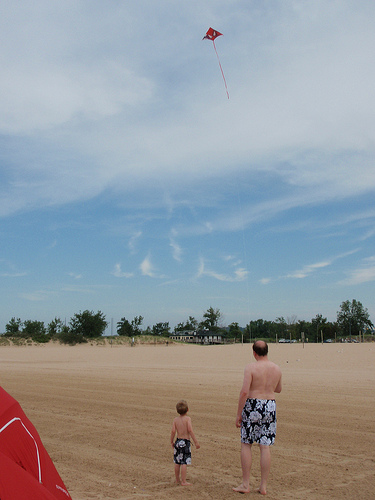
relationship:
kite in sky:
[201, 24, 231, 100] [0, 1, 374, 336]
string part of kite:
[211, 39, 231, 101] [201, 24, 231, 100]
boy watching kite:
[167, 398, 202, 487] [201, 24, 231, 100]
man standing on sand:
[234, 338, 283, 496] [0, 343, 374, 499]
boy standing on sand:
[167, 398, 202, 487] [0, 343, 374, 499]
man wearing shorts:
[234, 338, 283, 496] [239, 397, 277, 446]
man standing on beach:
[234, 338, 283, 496] [0, 343, 374, 499]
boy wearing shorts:
[167, 398, 202, 487] [174, 438, 193, 467]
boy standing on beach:
[167, 398, 202, 487] [0, 343, 374, 499]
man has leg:
[234, 338, 283, 496] [233, 441, 254, 494]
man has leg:
[234, 338, 283, 496] [257, 443, 270, 494]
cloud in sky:
[0, 0, 374, 215] [0, 1, 374, 336]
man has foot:
[234, 338, 283, 496] [230, 481, 251, 493]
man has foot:
[234, 338, 283, 496] [256, 485, 268, 495]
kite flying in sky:
[201, 24, 231, 100] [0, 1, 374, 336]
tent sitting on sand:
[1, 387, 71, 499] [0, 343, 374, 499]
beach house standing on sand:
[169, 327, 225, 343] [0, 343, 374, 499]